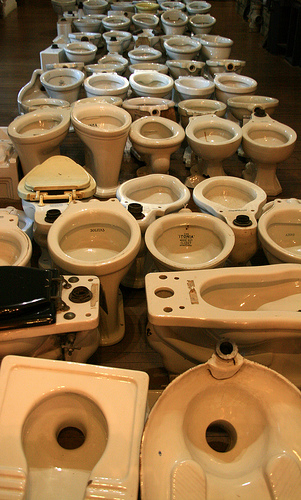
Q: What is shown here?
A: Toilet.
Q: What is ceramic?
A: All of the toilets.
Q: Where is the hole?
A: In the center of the toilet.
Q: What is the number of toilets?
A: Dozens.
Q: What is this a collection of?
A: Toilets.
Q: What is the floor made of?
A: Hardwood.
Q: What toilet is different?
A: The one with a lid.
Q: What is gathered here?
A: Lots of toilets.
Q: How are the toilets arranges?
A: In rows.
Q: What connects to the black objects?
A: Toilet tanks.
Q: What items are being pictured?
A: Toilets.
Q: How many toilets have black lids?
A: One.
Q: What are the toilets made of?
A: Porcelain.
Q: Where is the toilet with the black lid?
A: Left side.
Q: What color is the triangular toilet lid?
A: Off white.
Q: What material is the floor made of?
A: Wood.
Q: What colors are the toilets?
A: White and off white.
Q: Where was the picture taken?
A: At a toilet storage facility.